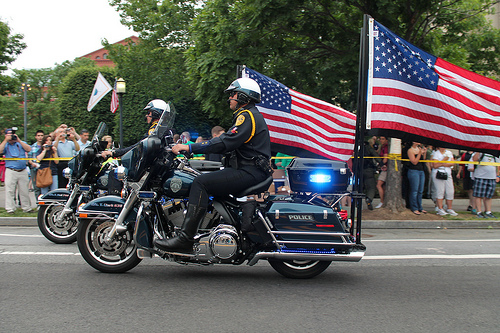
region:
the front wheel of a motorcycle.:
[71, 181, 160, 284]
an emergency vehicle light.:
[305, 168, 342, 189]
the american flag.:
[368, 11, 498, 158]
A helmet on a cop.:
[133, 93, 177, 140]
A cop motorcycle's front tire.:
[67, 188, 164, 282]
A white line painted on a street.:
[0, 243, 498, 262]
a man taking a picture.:
[0, 115, 36, 221]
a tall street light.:
[17, 69, 37, 145]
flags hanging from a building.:
[80, 65, 127, 127]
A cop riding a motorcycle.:
[75, 13, 498, 276]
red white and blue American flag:
[234, 53, 355, 181]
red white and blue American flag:
[346, 11, 498, 161]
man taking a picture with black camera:
[2, 125, 50, 187]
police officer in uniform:
[187, 66, 302, 256]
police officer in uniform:
[108, 86, 180, 191]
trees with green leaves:
[192, 3, 341, 87]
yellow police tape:
[410, 141, 499, 211]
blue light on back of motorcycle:
[291, 157, 344, 225]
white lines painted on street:
[381, 223, 493, 281]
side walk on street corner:
[400, 187, 494, 218]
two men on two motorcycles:
[28, 60, 377, 291]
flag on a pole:
[356, 8, 498, 168]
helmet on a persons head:
[221, 73, 266, 108]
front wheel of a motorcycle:
[67, 189, 160, 276]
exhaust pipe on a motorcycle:
[238, 240, 373, 275]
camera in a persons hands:
[4, 122, 23, 148]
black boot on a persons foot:
[149, 194, 213, 259]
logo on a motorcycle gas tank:
[165, 173, 187, 196]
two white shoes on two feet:
[432, 202, 462, 222]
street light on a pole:
[110, 72, 132, 110]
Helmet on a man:
[215, 66, 275, 121]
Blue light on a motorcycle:
[288, 147, 347, 207]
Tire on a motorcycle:
[72, 195, 157, 277]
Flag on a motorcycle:
[235, 61, 390, 164]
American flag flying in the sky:
[229, 56, 366, 173]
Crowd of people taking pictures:
[1, 126, 120, 232]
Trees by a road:
[58, 22, 393, 166]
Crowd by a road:
[387, 130, 497, 192]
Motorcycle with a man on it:
[94, 147, 345, 284]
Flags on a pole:
[86, 71, 148, 119]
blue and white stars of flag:
[372, 18, 440, 90]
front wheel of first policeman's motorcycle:
[75, 195, 145, 275]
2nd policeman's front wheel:
[32, 185, 88, 245]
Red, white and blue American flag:
[373, 17, 495, 157]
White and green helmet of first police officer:
[222, 75, 263, 98]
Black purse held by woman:
[432, 163, 449, 179]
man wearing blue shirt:
[2, 122, 38, 217]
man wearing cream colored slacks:
[0, 125, 37, 212]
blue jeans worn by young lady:
[406, 162, 423, 207]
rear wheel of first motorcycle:
[270, 250, 336, 280]